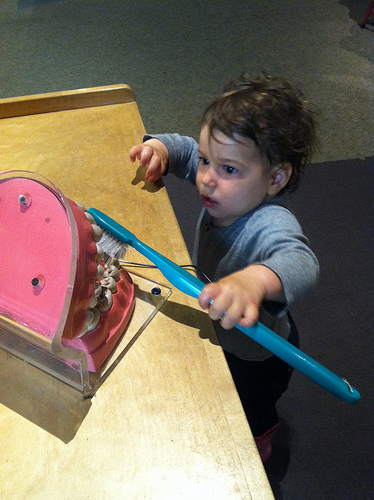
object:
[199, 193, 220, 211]
mouth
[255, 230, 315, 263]
wrinkles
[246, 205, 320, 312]
sleeve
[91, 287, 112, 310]
fake teeth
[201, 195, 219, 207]
lips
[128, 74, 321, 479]
baby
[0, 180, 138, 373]
pink gums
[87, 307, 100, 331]
teeth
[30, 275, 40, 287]
bolt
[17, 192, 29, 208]
bolt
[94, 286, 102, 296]
tooth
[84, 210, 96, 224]
tooth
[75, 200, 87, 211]
tooth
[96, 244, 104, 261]
tooth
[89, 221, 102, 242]
tooth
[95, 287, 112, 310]
teeth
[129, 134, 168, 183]
right hand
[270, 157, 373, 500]
carpet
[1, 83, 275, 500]
table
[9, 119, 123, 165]
wood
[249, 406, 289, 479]
shoe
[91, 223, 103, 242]
teeth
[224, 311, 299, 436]
pants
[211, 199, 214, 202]
teeth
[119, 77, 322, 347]
child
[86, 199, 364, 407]
brush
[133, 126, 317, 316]
shirt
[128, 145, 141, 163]
fingers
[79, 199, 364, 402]
tooth brush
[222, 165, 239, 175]
eye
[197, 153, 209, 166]
eye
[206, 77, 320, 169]
hair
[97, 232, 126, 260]
bristles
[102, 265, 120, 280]
teeth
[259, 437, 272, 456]
pink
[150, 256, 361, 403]
handle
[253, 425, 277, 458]
socks